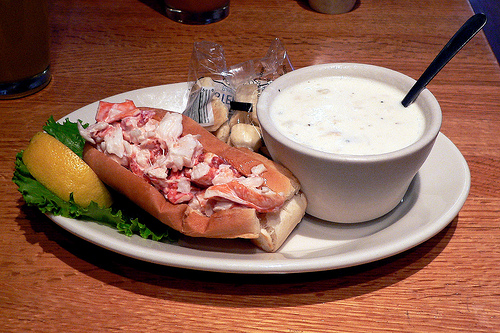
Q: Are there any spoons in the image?
A: Yes, there is a spoon.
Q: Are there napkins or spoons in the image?
A: Yes, there is a spoon.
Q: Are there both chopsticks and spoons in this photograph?
A: No, there is a spoon but no chopsticks.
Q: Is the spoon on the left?
A: No, the spoon is on the right of the image.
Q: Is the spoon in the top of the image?
A: Yes, the spoon is in the top of the image.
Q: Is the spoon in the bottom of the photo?
A: No, the spoon is in the top of the image.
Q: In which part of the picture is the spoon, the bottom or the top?
A: The spoon is in the top of the image.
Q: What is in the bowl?
A: The spoon is in the bowl.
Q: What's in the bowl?
A: The spoon is in the bowl.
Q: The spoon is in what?
A: The spoon is in the bowl.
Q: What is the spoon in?
A: The spoon is in the bowl.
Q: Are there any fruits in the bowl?
A: No, there is a spoon in the bowl.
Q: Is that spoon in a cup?
A: No, the spoon is in the bowl.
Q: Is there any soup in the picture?
A: Yes, there is soup.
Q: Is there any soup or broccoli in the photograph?
A: Yes, there is soup.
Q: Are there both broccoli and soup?
A: No, there is soup but no broccoli.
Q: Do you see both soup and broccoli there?
A: No, there is soup but no broccoli.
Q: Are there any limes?
A: No, there are no limes.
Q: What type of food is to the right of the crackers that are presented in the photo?
A: The food is soup.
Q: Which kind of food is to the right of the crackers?
A: The food is soup.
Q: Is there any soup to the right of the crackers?
A: Yes, there is soup to the right of the crackers.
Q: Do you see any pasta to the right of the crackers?
A: No, there is soup to the right of the crackers.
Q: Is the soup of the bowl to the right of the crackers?
A: Yes, the soup is to the right of the crackers.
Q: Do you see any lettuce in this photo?
A: Yes, there is lettuce.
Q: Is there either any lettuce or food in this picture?
A: Yes, there is lettuce.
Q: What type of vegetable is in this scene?
A: The vegetable is lettuce.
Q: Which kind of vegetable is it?
A: The vegetable is lettuce.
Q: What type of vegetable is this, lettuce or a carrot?
A: That is lettuce.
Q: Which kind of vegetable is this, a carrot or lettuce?
A: That is lettuce.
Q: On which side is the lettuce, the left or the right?
A: The lettuce is on the left of the image.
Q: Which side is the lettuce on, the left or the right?
A: The lettuce is on the left of the image.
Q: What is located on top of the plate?
A: The lettuce is on top of the plate.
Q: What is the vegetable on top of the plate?
A: The vegetable is lettuce.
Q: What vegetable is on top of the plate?
A: The vegetable is lettuce.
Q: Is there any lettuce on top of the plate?
A: Yes, there is lettuce on top of the plate.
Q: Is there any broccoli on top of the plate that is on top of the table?
A: No, there is lettuce on top of the plate.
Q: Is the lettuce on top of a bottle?
A: No, the lettuce is on top of the plate.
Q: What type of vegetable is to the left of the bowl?
A: The vegetable is lettuce.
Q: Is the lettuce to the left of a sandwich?
A: No, the lettuce is to the left of a bowl.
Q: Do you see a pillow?
A: No, there are no pillows.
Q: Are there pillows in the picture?
A: No, there are no pillows.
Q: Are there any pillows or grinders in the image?
A: No, there are no pillows or grinders.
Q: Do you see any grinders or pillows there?
A: No, there are no pillows or grinders.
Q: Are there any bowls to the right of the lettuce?
A: Yes, there is a bowl to the right of the lettuce.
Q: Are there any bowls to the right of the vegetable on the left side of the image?
A: Yes, there is a bowl to the right of the lettuce.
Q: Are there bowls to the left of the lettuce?
A: No, the bowl is to the right of the lettuce.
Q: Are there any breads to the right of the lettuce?
A: No, there is a bowl to the right of the lettuce.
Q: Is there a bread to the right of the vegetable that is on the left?
A: No, there is a bowl to the right of the lettuce.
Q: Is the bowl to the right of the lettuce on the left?
A: Yes, the bowl is to the right of the lettuce.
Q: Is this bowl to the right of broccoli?
A: No, the bowl is to the right of the lettuce.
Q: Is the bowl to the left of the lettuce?
A: No, the bowl is to the right of the lettuce.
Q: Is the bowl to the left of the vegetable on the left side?
A: No, the bowl is to the right of the lettuce.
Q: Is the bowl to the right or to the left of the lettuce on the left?
A: The bowl is to the right of the lettuce.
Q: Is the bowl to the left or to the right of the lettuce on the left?
A: The bowl is to the right of the lettuce.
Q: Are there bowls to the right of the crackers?
A: Yes, there is a bowl to the right of the crackers.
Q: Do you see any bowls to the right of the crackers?
A: Yes, there is a bowl to the right of the crackers.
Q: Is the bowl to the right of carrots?
A: No, the bowl is to the right of the crackers.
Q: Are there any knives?
A: No, there are no knives.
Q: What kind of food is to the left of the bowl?
A: The food is crackers.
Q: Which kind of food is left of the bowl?
A: The food is crackers.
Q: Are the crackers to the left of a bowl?
A: Yes, the crackers are to the left of a bowl.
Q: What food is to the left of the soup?
A: The food is crackers.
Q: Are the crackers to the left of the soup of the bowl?
A: Yes, the crackers are to the left of the soup.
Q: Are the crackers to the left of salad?
A: No, the crackers are to the left of the soup.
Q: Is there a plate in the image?
A: Yes, there is a plate.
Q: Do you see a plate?
A: Yes, there is a plate.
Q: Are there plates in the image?
A: Yes, there is a plate.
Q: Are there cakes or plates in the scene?
A: Yes, there is a plate.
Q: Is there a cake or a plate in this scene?
A: Yes, there is a plate.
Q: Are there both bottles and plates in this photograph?
A: No, there is a plate but no bottles.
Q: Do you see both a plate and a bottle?
A: No, there is a plate but no bottles.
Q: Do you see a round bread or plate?
A: Yes, there is a round plate.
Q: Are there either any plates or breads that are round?
A: Yes, the plate is round.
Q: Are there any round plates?
A: Yes, there is a round plate.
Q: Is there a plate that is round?
A: Yes, there is a plate that is round.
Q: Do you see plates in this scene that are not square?
A: Yes, there is a round plate.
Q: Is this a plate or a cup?
A: This is a plate.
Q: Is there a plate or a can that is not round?
A: No, there is a plate but it is round.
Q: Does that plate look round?
A: Yes, the plate is round.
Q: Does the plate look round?
A: Yes, the plate is round.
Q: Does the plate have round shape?
A: Yes, the plate is round.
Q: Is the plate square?
A: No, the plate is round.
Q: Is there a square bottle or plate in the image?
A: No, there is a plate but it is round.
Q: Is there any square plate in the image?
A: No, there is a plate but it is round.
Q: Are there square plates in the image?
A: No, there is a plate but it is round.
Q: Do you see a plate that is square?
A: No, there is a plate but it is round.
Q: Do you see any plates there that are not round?
A: No, there is a plate but it is round.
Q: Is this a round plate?
A: Yes, this is a round plate.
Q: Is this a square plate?
A: No, this is a round plate.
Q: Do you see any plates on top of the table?
A: Yes, there is a plate on top of the table.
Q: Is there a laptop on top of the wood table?
A: No, there is a plate on top of the table.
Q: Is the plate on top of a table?
A: Yes, the plate is on top of a table.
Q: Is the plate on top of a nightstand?
A: No, the plate is on top of a table.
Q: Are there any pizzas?
A: No, there are no pizzas.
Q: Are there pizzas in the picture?
A: No, there are no pizzas.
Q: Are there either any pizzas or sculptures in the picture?
A: No, there are no pizzas or sculptures.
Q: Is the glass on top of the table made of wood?
A: Yes, the glass is on top of the table.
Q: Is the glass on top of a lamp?
A: No, the glass is on top of the table.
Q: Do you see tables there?
A: Yes, there is a table.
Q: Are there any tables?
A: Yes, there is a table.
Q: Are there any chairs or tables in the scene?
A: Yes, there is a table.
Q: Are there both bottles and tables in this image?
A: No, there is a table but no bottles.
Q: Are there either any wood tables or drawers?
A: Yes, there is a wood table.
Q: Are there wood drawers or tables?
A: Yes, there is a wood table.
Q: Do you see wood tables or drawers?
A: Yes, there is a wood table.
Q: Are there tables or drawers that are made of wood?
A: Yes, the table is made of wood.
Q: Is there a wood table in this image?
A: Yes, there is a wood table.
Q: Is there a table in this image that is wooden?
A: Yes, there is a table that is wooden.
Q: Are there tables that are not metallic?
A: Yes, there is a wooden table.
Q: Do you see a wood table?
A: Yes, there is a table that is made of wood.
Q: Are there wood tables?
A: Yes, there is a table that is made of wood.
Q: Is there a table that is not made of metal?
A: Yes, there is a table that is made of wood.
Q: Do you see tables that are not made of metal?
A: Yes, there is a table that is made of wood.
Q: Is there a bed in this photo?
A: No, there are no beds.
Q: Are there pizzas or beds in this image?
A: No, there are no beds or pizzas.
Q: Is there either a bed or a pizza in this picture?
A: No, there are no beds or pizzas.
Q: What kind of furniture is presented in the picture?
A: The furniture is a table.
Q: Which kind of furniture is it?
A: The piece of furniture is a table.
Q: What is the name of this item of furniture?
A: This is a table.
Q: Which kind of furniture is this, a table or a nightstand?
A: This is a table.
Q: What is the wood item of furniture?
A: The piece of furniture is a table.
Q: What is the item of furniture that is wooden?
A: The piece of furniture is a table.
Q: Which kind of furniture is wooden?
A: The furniture is a table.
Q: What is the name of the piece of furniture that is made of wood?
A: The piece of furniture is a table.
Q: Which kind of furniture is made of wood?
A: The furniture is a table.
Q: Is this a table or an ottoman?
A: This is a table.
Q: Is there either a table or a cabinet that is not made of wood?
A: No, there is a table but it is made of wood.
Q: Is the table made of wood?
A: Yes, the table is made of wood.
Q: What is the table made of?
A: The table is made of wood.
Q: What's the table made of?
A: The table is made of wood.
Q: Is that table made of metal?
A: No, the table is made of wood.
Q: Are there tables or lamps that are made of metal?
A: No, there is a table but it is made of wood.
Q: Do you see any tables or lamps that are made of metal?
A: No, there is a table but it is made of wood.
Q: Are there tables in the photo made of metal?
A: No, there is a table but it is made of wood.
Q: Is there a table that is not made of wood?
A: No, there is a table but it is made of wood.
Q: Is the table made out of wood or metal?
A: The table is made of wood.